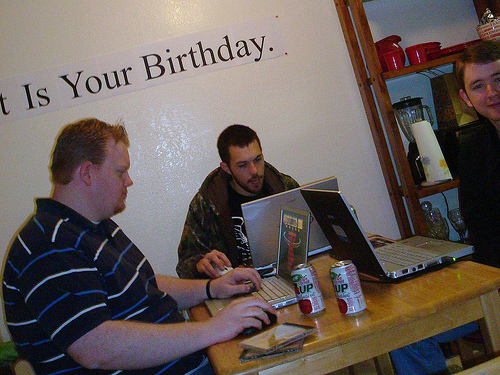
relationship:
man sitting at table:
[2, 119, 279, 372] [191, 236, 498, 374]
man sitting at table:
[392, 43, 499, 374] [191, 236, 498, 374]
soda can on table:
[290, 264, 326, 317] [191, 236, 498, 374]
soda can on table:
[328, 258, 366, 316] [191, 236, 498, 374]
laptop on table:
[301, 187, 476, 282] [191, 236, 498, 374]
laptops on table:
[202, 209, 313, 320] [191, 236, 498, 374]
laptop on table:
[239, 177, 346, 278] [191, 236, 498, 374]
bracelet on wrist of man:
[204, 278, 213, 301] [2, 119, 279, 372]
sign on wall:
[1, 22, 283, 124] [0, 0, 410, 344]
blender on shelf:
[392, 94, 435, 183] [336, 0, 499, 250]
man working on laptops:
[2, 119, 279, 372] [202, 209, 313, 320]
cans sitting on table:
[290, 262, 365, 315] [191, 236, 498, 374]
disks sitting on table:
[240, 322, 317, 364] [191, 236, 498, 374]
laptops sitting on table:
[206, 177, 471, 320] [191, 236, 498, 374]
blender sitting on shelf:
[392, 94, 435, 183] [336, 0, 499, 250]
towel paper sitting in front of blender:
[411, 120, 452, 185] [392, 94, 435, 183]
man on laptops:
[2, 119, 279, 372] [202, 209, 313, 320]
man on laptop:
[392, 43, 499, 374] [301, 187, 476, 282]